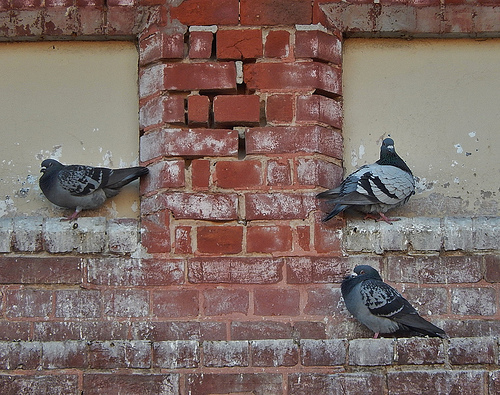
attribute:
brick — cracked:
[219, 26, 271, 63]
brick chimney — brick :
[139, 36, 345, 226]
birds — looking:
[7, 122, 485, 350]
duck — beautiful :
[341, 264, 448, 338]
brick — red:
[215, 28, 262, 60]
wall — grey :
[3, 39, 499, 216]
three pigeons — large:
[3, 109, 425, 393]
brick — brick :
[210, 157, 269, 189]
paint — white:
[62, 136, 133, 168]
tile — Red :
[215, 28, 262, 59]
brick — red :
[213, 87, 263, 123]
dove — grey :
[314, 131, 413, 227]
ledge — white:
[343, 209, 498, 254]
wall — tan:
[347, 40, 499, 226]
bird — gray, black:
[35, 153, 145, 220]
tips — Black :
[358, 171, 388, 202]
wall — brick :
[5, 13, 492, 393]